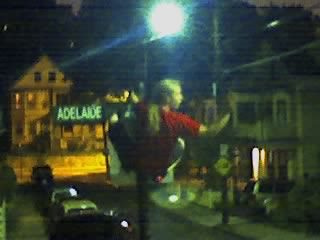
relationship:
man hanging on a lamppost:
[106, 79, 231, 179] [143, 36, 171, 104]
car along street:
[44, 211, 130, 240] [28, 173, 240, 239]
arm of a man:
[175, 109, 230, 142] [106, 79, 231, 179]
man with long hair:
[106, 79, 231, 179] [143, 80, 184, 138]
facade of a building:
[7, 51, 74, 152] [8, 54, 78, 156]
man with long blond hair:
[106, 79, 231, 179] [143, 80, 184, 138]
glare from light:
[57, 25, 147, 69] [140, 1, 198, 43]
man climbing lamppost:
[106, 79, 231, 179] [143, 36, 171, 104]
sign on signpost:
[215, 157, 233, 176] [221, 172, 229, 222]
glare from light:
[253, 180, 258, 195] [260, 148, 264, 166]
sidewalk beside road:
[152, 188, 320, 240] [28, 173, 240, 239]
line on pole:
[224, 41, 317, 76] [214, 40, 224, 123]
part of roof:
[9, 69, 26, 86] [8, 51, 44, 90]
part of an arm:
[197, 123, 208, 137] [175, 109, 230, 142]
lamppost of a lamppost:
[136, 36, 154, 240] [136, 36, 154, 240]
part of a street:
[145, 185, 245, 238] [28, 173, 240, 239]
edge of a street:
[153, 198, 240, 239] [28, 173, 240, 239]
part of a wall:
[109, 166, 121, 175] [105, 136, 135, 186]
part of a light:
[168, 0, 193, 15] [140, 1, 198, 43]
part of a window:
[28, 101, 34, 107] [27, 93, 35, 110]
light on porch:
[244, 143, 270, 186] [240, 146, 299, 191]